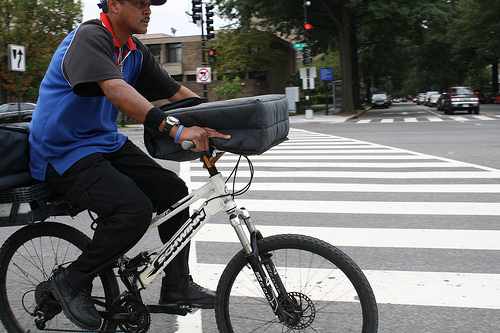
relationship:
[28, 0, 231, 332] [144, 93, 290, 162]
man delivering pizza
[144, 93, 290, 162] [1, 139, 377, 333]
pizza delivered on bike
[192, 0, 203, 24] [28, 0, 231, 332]
traffic signal behind man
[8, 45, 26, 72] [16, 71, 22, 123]
sign attached to pole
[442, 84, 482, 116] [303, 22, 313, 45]
car waiting at traffic signal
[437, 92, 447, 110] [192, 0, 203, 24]
car waiting at traffic signal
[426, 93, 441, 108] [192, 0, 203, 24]
car waiting at traffic signal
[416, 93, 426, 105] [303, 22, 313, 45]
car waiting at traffic signal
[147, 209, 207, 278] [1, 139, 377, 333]
logo painted on bike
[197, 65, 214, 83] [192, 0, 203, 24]
sign near traffic signal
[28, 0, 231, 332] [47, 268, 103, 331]
man wearing shoe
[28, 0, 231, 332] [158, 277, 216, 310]
man wearing shoe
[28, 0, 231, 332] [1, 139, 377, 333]
man riding bike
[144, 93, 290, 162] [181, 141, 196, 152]
pizza balanced on handle bar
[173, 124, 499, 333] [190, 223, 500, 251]
crosswalk has line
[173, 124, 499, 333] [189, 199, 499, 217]
crosswalk has line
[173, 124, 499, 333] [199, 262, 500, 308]
crosswalk has line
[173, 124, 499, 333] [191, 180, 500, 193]
crosswalk has line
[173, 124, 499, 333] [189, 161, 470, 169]
crosswalk has line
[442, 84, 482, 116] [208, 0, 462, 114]
car to right of tree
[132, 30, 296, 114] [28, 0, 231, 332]
building behind man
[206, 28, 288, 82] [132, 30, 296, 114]
tree in front of building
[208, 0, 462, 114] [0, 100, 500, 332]
tree next to street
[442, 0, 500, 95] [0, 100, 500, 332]
tree next to street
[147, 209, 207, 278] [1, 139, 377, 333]
logo written on bike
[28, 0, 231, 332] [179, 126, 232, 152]
man has hand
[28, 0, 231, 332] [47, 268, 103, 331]
man has shoe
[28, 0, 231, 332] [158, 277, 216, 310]
man has shoe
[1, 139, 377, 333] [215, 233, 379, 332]
bike has tire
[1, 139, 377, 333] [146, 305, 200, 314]
bike has pedal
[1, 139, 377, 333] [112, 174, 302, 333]
bike has frame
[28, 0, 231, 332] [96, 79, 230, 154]
man has arm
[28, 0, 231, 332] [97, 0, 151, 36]
man has head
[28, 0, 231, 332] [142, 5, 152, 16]
man has nose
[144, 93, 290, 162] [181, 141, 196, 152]
pizza resting on handle bar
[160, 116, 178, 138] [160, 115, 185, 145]
watch worn on wrist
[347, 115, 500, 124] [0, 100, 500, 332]
crosswalk located in street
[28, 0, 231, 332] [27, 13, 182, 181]
man wearing shirt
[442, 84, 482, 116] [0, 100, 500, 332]
car on top of street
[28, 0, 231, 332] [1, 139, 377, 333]
man on top of bike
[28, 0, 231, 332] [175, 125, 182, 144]
man wearing wristband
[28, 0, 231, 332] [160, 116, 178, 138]
man wearing watch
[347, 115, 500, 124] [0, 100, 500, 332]
crosswalk painted on street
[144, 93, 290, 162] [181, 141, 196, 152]
pizza on top of handle bar